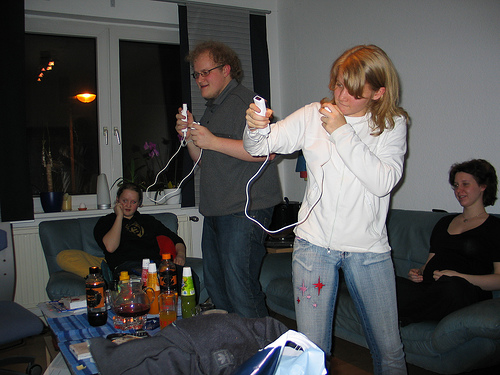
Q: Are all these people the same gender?
A: No, they are both male and female.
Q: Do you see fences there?
A: No, there are no fences.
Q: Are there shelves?
A: No, there are no shelves.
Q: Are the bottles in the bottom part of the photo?
A: Yes, the bottles are in the bottom of the image.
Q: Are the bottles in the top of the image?
A: No, the bottles are in the bottom of the image.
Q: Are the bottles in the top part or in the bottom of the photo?
A: The bottles are in the bottom of the image.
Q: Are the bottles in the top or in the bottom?
A: The bottles are in the bottom of the image.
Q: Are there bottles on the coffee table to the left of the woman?
A: Yes, there are bottles on the coffee table.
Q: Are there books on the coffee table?
A: No, there are bottles on the coffee table.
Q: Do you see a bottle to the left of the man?
A: Yes, there are bottles to the left of the man.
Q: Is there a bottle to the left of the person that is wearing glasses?
A: Yes, there are bottles to the left of the man.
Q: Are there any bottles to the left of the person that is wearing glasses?
A: Yes, there are bottles to the left of the man.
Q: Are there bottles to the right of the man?
A: No, the bottles are to the left of the man.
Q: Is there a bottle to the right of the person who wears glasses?
A: No, the bottles are to the left of the man.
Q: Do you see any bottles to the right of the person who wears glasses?
A: No, the bottles are to the left of the man.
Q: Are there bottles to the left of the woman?
A: Yes, there are bottles to the left of the woman.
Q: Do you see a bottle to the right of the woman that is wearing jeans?
A: No, the bottles are to the left of the woman.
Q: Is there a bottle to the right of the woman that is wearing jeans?
A: No, the bottles are to the left of the woman.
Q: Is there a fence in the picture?
A: No, there are no fences.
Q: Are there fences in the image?
A: No, there are no fences.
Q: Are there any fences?
A: No, there are no fences.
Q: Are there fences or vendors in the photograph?
A: No, there are no fences or vendors.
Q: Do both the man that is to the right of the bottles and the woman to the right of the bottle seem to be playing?
A: Yes, both the man and the woman are playing.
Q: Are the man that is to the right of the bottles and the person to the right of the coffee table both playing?
A: Yes, both the man and the woman are playing.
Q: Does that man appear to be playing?
A: Yes, the man is playing.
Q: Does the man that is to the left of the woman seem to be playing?
A: Yes, the man is playing.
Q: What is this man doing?
A: The man is playing.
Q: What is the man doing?
A: The man is playing.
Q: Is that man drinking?
A: No, the man is playing.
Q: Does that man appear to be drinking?
A: No, the man is playing.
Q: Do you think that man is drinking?
A: No, the man is playing.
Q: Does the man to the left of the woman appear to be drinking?
A: No, the man is playing.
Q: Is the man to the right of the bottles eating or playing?
A: The man is playing.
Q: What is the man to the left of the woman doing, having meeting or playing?
A: The man is playing.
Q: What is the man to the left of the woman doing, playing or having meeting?
A: The man is playing.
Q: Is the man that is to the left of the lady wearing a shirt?
A: Yes, the man is wearing a shirt.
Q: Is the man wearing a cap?
A: No, the man is wearing a shirt.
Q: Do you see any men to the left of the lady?
A: Yes, there is a man to the left of the lady.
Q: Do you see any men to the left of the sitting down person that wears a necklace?
A: Yes, there is a man to the left of the lady.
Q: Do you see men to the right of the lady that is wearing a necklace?
A: No, the man is to the left of the lady.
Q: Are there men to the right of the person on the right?
A: No, the man is to the left of the lady.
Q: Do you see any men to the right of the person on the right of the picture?
A: No, the man is to the left of the lady.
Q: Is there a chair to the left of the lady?
A: No, there is a man to the left of the lady.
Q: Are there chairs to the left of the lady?
A: No, there is a man to the left of the lady.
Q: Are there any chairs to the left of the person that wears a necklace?
A: No, there is a man to the left of the lady.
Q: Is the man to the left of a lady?
A: Yes, the man is to the left of a lady.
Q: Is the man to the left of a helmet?
A: No, the man is to the left of a lady.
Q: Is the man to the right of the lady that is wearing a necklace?
A: No, the man is to the left of the lady.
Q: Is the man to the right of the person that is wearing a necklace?
A: No, the man is to the left of the lady.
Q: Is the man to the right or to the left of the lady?
A: The man is to the left of the lady.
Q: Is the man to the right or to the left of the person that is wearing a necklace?
A: The man is to the left of the lady.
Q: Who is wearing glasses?
A: The man is wearing glasses.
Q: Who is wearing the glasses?
A: The man is wearing glasses.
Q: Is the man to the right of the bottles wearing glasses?
A: Yes, the man is wearing glasses.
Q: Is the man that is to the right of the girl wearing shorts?
A: No, the man is wearing glasses.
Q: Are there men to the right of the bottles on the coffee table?
A: Yes, there is a man to the right of the bottles.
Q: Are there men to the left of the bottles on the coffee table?
A: No, the man is to the right of the bottles.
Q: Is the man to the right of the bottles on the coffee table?
A: Yes, the man is to the right of the bottles.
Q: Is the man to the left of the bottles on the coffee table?
A: No, the man is to the right of the bottles.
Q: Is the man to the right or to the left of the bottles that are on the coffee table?
A: The man is to the right of the bottles.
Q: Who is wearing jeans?
A: The man is wearing jeans.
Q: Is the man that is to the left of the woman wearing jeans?
A: Yes, the man is wearing jeans.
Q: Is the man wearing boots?
A: No, the man is wearing jeans.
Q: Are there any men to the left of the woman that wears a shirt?
A: Yes, there is a man to the left of the woman.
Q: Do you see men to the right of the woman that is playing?
A: No, the man is to the left of the woman.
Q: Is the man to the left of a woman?
A: Yes, the man is to the left of a woman.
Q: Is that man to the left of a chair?
A: No, the man is to the left of a woman.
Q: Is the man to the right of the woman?
A: No, the man is to the left of the woman.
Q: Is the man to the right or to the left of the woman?
A: The man is to the left of the woman.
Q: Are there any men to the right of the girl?
A: Yes, there is a man to the right of the girl.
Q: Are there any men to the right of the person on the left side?
A: Yes, there is a man to the right of the girl.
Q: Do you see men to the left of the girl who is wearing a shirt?
A: No, the man is to the right of the girl.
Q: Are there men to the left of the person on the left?
A: No, the man is to the right of the girl.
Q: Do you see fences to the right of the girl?
A: No, there is a man to the right of the girl.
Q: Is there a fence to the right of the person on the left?
A: No, there is a man to the right of the girl.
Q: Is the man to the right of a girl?
A: Yes, the man is to the right of a girl.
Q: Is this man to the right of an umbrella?
A: No, the man is to the right of a girl.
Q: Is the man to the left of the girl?
A: No, the man is to the right of the girl.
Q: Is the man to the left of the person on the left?
A: No, the man is to the right of the girl.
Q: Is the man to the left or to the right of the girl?
A: The man is to the right of the girl.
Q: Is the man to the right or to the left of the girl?
A: The man is to the right of the girl.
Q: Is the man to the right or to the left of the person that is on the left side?
A: The man is to the right of the girl.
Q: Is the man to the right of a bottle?
A: Yes, the man is to the right of a bottle.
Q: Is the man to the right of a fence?
A: No, the man is to the right of a bottle.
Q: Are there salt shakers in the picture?
A: No, there are no salt shakers.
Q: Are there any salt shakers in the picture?
A: No, there are no salt shakers.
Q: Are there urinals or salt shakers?
A: No, there are no salt shakers or urinals.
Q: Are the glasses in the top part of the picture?
A: Yes, the glasses are in the top of the image.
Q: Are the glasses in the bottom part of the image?
A: No, the glasses are in the top of the image.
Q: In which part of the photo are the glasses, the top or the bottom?
A: The glasses are in the top of the image.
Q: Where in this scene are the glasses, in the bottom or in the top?
A: The glasses are in the top of the image.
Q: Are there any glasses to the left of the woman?
A: Yes, there are glasses to the left of the woman.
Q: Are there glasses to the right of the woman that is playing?
A: No, the glasses are to the left of the woman.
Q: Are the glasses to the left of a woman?
A: Yes, the glasses are to the left of a woman.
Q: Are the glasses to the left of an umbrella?
A: No, the glasses are to the left of a woman.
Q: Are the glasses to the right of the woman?
A: No, the glasses are to the left of the woman.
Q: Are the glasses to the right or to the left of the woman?
A: The glasses are to the left of the woman.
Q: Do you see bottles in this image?
A: Yes, there is a bottle.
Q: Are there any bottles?
A: Yes, there is a bottle.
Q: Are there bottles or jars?
A: Yes, there is a bottle.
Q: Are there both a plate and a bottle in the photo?
A: No, there is a bottle but no plates.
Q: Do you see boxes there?
A: No, there are no boxes.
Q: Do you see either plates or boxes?
A: No, there are no boxes or plates.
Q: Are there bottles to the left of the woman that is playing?
A: Yes, there is a bottle to the left of the woman.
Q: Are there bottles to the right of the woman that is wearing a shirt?
A: No, the bottle is to the left of the woman.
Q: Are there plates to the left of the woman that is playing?
A: No, there is a bottle to the left of the woman.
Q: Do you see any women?
A: Yes, there is a woman.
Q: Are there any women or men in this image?
A: Yes, there is a woman.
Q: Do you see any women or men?
A: Yes, there is a woman.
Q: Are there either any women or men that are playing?
A: Yes, the woman is playing.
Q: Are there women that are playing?
A: Yes, there is a woman that is playing.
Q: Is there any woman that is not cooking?
A: Yes, there is a woman that is playing.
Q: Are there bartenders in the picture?
A: No, there are no bartenders.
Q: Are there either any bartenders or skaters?
A: No, there are no bartenders or skaters.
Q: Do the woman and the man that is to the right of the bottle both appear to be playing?
A: Yes, both the woman and the man are playing.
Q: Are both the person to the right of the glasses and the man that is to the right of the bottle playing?
A: Yes, both the woman and the man are playing.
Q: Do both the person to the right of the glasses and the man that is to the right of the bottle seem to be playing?
A: Yes, both the woman and the man are playing.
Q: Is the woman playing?
A: Yes, the woman is playing.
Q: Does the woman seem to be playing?
A: Yes, the woman is playing.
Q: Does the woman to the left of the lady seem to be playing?
A: Yes, the woman is playing.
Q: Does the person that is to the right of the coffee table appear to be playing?
A: Yes, the woman is playing.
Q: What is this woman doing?
A: The woman is playing.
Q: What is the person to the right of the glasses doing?
A: The woman is playing.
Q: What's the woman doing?
A: The woman is playing.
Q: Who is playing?
A: The woman is playing.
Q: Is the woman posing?
A: No, the woman is playing.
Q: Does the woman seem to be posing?
A: No, the woman is playing.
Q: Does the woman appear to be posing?
A: No, the woman is playing.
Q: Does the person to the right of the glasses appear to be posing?
A: No, the woman is playing.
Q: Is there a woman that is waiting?
A: No, there is a woman but she is playing.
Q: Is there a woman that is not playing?
A: No, there is a woman but she is playing.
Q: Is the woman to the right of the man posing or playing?
A: The woman is playing.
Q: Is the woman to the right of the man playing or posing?
A: The woman is playing.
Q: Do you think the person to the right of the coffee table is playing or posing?
A: The woman is playing.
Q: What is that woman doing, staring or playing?
A: The woman is playing.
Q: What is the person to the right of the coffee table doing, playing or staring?
A: The woman is playing.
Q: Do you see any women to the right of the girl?
A: Yes, there is a woman to the right of the girl.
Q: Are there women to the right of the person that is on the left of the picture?
A: Yes, there is a woman to the right of the girl.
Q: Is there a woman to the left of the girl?
A: No, the woman is to the right of the girl.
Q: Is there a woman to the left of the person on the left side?
A: No, the woman is to the right of the girl.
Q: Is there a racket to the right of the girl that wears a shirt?
A: No, there is a woman to the right of the girl.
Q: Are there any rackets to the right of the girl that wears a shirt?
A: No, there is a woman to the right of the girl.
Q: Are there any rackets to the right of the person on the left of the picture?
A: No, there is a woman to the right of the girl.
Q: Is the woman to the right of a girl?
A: Yes, the woman is to the right of a girl.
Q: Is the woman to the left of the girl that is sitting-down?
A: No, the woman is to the right of the girl.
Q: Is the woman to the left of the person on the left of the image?
A: No, the woman is to the right of the girl.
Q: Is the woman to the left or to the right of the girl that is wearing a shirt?
A: The woman is to the right of the girl.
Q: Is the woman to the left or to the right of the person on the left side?
A: The woman is to the right of the girl.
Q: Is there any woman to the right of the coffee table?
A: Yes, there is a woman to the right of the coffee table.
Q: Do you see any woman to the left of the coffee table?
A: No, the woman is to the right of the coffee table.